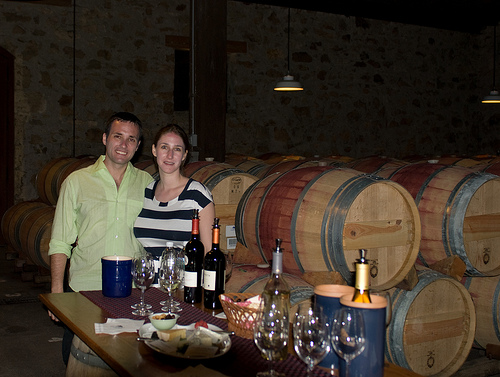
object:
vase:
[101, 240, 182, 350]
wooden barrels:
[222, 158, 446, 280]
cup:
[100, 252, 136, 299]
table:
[36, 257, 425, 374]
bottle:
[184, 208, 204, 303]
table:
[38, 287, 425, 374]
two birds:
[92, 309, 147, 338]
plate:
[136, 303, 235, 360]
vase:
[102, 253, 130, 296]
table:
[37, 279, 389, 375]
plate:
[137, 308, 225, 361]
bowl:
[149, 313, 180, 330]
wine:
[200, 215, 232, 310]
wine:
[180, 207, 204, 300]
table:
[34, 277, 313, 375]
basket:
[216, 292, 265, 338]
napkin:
[217, 291, 264, 322]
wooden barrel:
[237, 163, 405, 308]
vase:
[75, 247, 134, 302]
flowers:
[149, 297, 251, 356]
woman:
[133, 123, 216, 299]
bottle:
[353, 247, 372, 302]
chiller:
[333, 293, 386, 376]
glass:
[124, 242, 165, 324]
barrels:
[200, 151, 498, 337]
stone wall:
[297, 33, 446, 150]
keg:
[296, 163, 411, 285]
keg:
[401, 151, 488, 275]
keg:
[383, 283, 473, 367]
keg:
[469, 282, 497, 334]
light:
[264, 6, 316, 96]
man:
[38, 102, 146, 288]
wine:
[181, 209, 223, 304]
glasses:
[330, 310, 361, 369]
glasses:
[295, 304, 333, 374]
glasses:
[253, 303, 290, 375]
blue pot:
[334, 300, 389, 377]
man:
[36, 109, 158, 294]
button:
[116, 218, 119, 220]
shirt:
[40, 155, 157, 289]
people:
[60, 117, 222, 284]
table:
[59, 293, 123, 347]